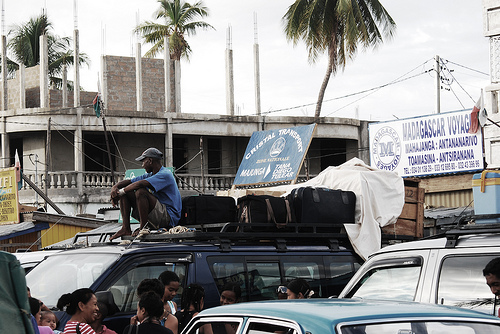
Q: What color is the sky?
A: White.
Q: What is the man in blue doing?
A: Sitting on top of the car.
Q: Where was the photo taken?
A: In the city.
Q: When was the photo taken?
A: Daytime.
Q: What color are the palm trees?
A: Green.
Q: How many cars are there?
A: Three.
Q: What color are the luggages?
A: Black.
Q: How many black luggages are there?
A: Three.